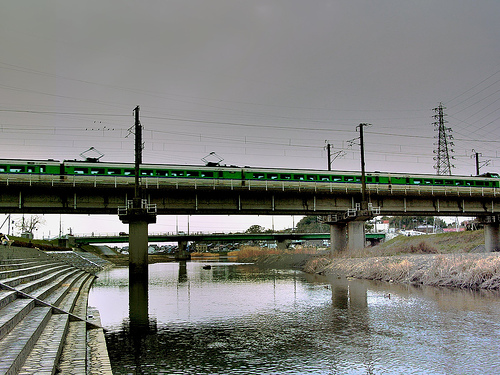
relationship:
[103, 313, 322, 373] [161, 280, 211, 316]
reflection of water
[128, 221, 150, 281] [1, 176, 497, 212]
pier of bridge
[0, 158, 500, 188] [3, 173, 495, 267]
train crossing bridge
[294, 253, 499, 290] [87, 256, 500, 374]
grass along a water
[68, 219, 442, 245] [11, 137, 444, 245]
buildings behind bridge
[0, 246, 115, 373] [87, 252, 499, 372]
steps by water body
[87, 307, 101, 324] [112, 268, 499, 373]
concrete step along river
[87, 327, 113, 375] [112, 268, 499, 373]
concrete step along river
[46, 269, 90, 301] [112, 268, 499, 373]
concrete step along river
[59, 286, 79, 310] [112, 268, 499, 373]
concrete step along river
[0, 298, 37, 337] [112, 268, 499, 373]
concrete step along river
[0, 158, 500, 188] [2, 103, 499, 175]
train has wiring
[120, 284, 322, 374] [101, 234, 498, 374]
reflection on water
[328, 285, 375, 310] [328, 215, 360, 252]
reflections on columns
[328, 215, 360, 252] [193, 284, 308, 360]
columns on water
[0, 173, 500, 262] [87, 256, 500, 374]
bridges are over water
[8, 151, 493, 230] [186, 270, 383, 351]
pier reflected in water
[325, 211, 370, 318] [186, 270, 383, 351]
pier reflected in water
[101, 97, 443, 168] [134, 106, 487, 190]
wires attached to poles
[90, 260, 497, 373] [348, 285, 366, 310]
water has reflections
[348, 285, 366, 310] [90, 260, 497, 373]
reflections on water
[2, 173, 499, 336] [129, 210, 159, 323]
bridges supported by pier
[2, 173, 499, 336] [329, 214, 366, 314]
bridges supported by pier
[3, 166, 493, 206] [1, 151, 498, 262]
train on bridge